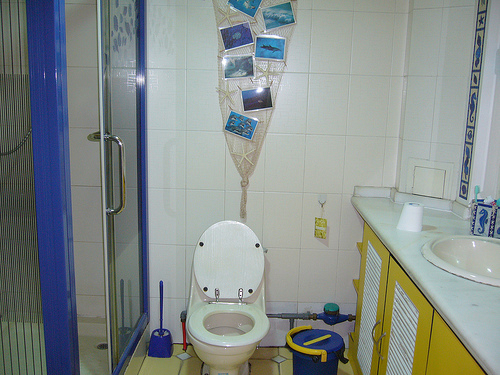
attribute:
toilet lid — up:
[190, 220, 265, 300]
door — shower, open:
[91, 2, 148, 374]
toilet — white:
[183, 217, 269, 373]